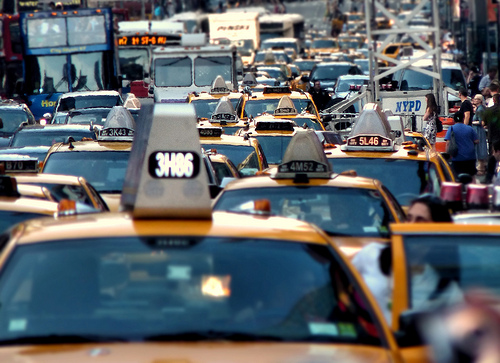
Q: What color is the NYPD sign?
A: White.